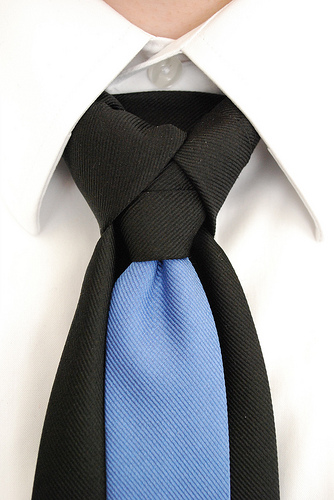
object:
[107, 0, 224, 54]
man's race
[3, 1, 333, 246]
collar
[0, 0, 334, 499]
shirt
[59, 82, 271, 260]
loop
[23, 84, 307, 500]
necktie